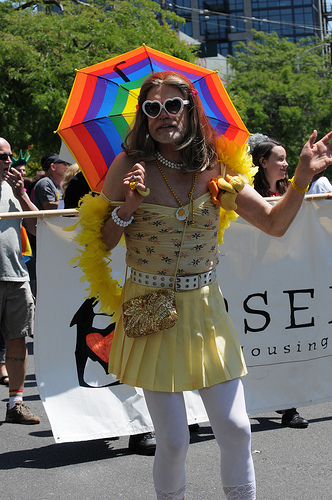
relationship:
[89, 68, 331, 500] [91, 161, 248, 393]
man wearing dress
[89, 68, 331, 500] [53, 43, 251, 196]
man holding umbrella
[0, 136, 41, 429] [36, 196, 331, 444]
person walking behind banner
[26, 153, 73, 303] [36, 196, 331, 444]
person walking behind banner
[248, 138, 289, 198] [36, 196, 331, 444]
person walking behind banner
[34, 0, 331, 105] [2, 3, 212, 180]
building behind trees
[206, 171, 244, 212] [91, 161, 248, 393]
stuffed animal attached to dress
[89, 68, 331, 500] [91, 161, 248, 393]
man in dress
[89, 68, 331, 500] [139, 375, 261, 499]
man in leggings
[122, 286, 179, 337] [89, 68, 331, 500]
purse of man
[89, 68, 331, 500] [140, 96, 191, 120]
man wearing sunglasses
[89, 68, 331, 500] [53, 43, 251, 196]
man carrying umbrella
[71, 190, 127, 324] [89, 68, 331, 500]
boa on man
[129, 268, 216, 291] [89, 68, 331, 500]
belt on man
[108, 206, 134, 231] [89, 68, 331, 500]
bracelet on man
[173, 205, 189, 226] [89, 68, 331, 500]
daisy pin on man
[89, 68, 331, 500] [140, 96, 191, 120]
man with sunglasses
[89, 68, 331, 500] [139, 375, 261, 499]
man with leggings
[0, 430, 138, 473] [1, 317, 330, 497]
shadow on ground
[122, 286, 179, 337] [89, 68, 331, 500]
purse on man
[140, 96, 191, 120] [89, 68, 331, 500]
sunglasses on man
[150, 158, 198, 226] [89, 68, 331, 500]
necklace on man